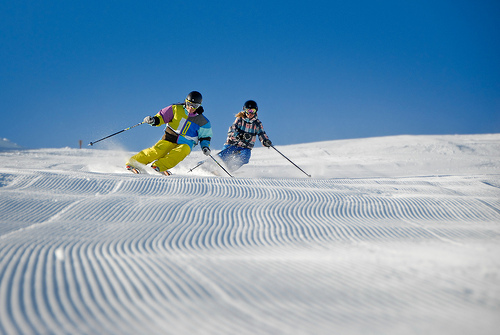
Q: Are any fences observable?
A: No, there are no fences.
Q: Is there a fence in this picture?
A: No, there are no fences.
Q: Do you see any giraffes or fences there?
A: No, there are no fences or giraffes.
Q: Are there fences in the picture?
A: No, there are no fences.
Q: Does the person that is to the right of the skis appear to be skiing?
A: Yes, the person is skiing.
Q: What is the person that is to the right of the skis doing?
A: The person is skiing.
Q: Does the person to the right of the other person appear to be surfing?
A: No, the person is skiing.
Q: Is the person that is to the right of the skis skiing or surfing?
A: The person is skiing.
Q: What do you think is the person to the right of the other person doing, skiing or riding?
A: The person is skiing.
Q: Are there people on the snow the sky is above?
A: Yes, there is a person on the snow.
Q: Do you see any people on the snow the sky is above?
A: Yes, there is a person on the snow.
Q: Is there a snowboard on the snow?
A: No, there is a person on the snow.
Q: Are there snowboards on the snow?
A: No, there is a person on the snow.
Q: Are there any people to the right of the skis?
A: Yes, there is a person to the right of the skis.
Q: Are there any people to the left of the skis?
A: No, the person is to the right of the skis.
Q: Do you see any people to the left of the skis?
A: No, the person is to the right of the skis.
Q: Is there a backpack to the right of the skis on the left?
A: No, there is a person to the right of the skis.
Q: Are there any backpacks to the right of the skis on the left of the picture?
A: No, there is a person to the right of the skis.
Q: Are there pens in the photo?
A: No, there are no pens.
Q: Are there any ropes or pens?
A: No, there are no pens or ropes.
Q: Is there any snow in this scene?
A: Yes, there is snow.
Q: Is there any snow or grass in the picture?
A: Yes, there is snow.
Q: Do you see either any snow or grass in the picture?
A: Yes, there is snow.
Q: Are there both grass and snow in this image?
A: No, there is snow but no grass.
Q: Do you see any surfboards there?
A: No, there are no surfboards.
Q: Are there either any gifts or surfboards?
A: No, there are no surfboards or gifts.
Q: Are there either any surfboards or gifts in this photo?
A: No, there are no surfboards or gifts.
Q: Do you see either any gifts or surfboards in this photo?
A: No, there are no surfboards or gifts.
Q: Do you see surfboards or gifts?
A: No, there are no surfboards or gifts.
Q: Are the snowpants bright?
A: Yes, the snowpants are bright.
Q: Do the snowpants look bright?
A: Yes, the snowpants are bright.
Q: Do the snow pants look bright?
A: Yes, the snow pants are bright.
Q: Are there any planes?
A: No, there are no planes.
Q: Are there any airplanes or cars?
A: No, there are no airplanes or cars.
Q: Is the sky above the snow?
A: Yes, the sky is above the snow.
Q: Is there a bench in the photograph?
A: No, there are no benches.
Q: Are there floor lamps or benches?
A: No, there are no benches or floor lamps.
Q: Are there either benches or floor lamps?
A: No, there are no benches or floor lamps.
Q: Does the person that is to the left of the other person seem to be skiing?
A: Yes, the person is skiing.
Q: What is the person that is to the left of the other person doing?
A: The person is skiing.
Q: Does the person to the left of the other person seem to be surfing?
A: No, the person is skiing.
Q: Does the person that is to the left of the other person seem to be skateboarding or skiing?
A: The person is skiing.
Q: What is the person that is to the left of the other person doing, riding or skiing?
A: The person is skiing.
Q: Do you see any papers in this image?
A: No, there are no papers.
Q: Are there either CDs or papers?
A: No, there are no papers or cds.